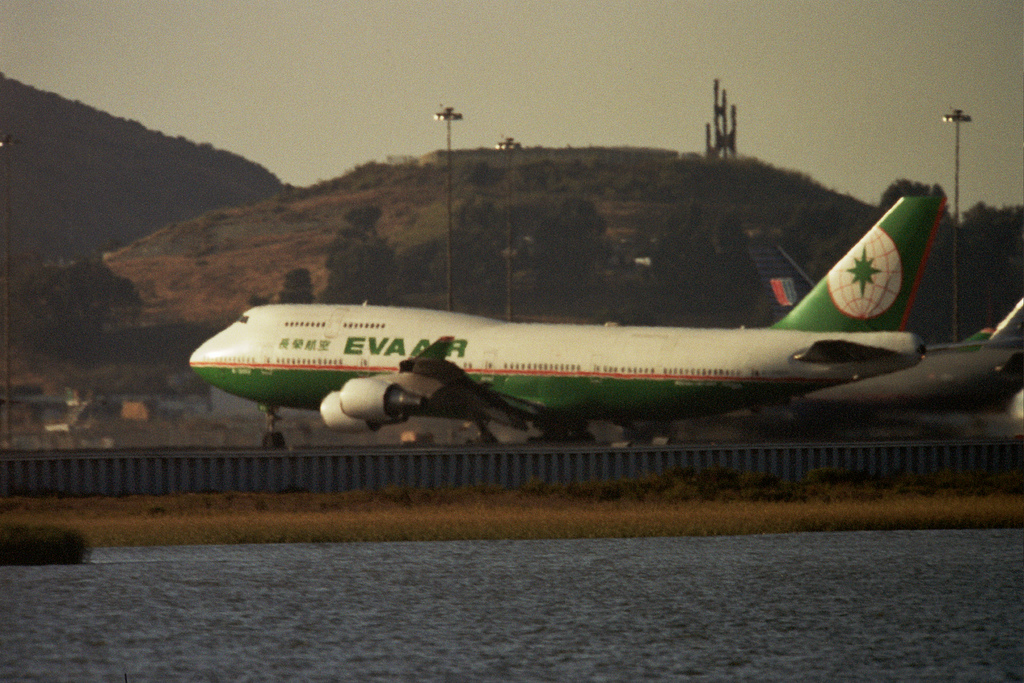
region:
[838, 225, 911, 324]
tail of the plane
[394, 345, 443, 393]
wing on the plane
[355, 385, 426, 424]
eingine on the plane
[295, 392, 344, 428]
engine on thep lane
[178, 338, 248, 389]
nose of the plane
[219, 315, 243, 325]
window on the plane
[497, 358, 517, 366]
window on the plane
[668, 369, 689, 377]
window on the plane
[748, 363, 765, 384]
window on the plane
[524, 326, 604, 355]
the plane is white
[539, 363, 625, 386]
the line is red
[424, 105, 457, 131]
the light is on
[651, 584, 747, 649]
the water has a lot of waves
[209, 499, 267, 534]
the grass is brown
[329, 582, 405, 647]
the water is blue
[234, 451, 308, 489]
the barrier is gray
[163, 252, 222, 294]
the hillside is brown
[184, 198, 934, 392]
A green, white and red plane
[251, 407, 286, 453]
Plane landing gear wheels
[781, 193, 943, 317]
The tail of the plane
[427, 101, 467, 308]
A lamp pole with lights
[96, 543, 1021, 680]
A large body of water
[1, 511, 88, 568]
A small bush in the water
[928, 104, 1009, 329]
A lamp pole in the back of the plane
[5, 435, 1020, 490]
A black fence rail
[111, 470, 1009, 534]
A large field of grass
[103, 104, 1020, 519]
The plane is green and white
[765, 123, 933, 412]
A red circle on the back of the plne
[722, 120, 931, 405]
A green star is inside the red circle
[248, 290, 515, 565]
The plane engine is white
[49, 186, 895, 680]
The plane is near the water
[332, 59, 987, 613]
The hill is behind the plane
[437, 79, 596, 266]
A house at the top of the hill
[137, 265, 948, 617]
A fence is between the plane and water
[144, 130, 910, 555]
A red stripe is going down the side of the plane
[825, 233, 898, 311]
Green compass sign on the tail.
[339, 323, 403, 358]
Large green letters on the side of the plane.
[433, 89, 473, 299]
Large light pole in the ground.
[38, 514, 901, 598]
Small body of still water.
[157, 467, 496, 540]
Trail of sand by the water.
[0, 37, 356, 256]
Small mountain on the side of the hill.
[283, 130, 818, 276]
Large hill behind the plane.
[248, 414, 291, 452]
Small black tire underneath the plane.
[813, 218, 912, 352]
Large black and white globe on the tail.